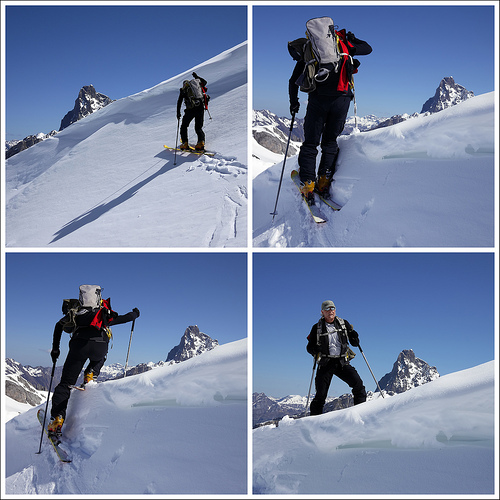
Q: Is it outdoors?
A: Yes, it is outdoors.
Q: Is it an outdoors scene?
A: Yes, it is outdoors.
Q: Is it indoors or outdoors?
A: It is outdoors.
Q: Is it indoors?
A: No, it is outdoors.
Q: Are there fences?
A: No, there are no fences.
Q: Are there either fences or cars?
A: No, there are no fences or cars.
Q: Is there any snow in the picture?
A: Yes, there is snow.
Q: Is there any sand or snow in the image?
A: Yes, there is snow.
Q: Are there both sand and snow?
A: No, there is snow but no sand.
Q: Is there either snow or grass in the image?
A: Yes, there is snow.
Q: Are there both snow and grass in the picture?
A: No, there is snow but no grass.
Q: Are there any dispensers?
A: No, there are no dispensers.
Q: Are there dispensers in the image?
A: No, there are no dispensers.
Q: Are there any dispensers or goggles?
A: No, there are no dispensers or goggles.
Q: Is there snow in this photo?
A: Yes, there is snow.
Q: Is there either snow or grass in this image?
A: Yes, there is snow.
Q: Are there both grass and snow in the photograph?
A: No, there is snow but no grass.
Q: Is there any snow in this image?
A: Yes, there is snow.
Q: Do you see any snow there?
A: Yes, there is snow.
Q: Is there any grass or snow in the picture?
A: Yes, there is snow.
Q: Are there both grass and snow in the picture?
A: No, there is snow but no grass.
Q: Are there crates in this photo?
A: No, there are no crates.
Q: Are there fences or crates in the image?
A: No, there are no crates or fences.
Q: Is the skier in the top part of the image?
A: Yes, the skier is in the top of the image.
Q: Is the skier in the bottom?
A: No, the skier is in the top of the image.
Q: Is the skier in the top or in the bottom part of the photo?
A: The skier is in the top of the image.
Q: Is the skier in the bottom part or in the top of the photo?
A: The skier is in the top of the image.